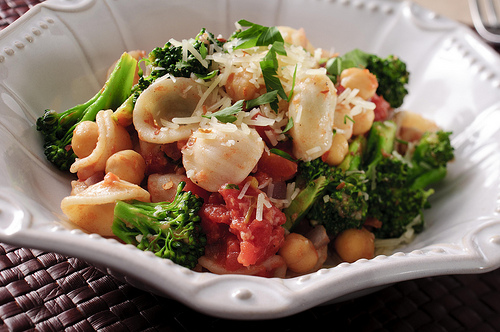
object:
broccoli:
[322, 49, 411, 108]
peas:
[280, 230, 320, 272]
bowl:
[0, 1, 500, 320]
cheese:
[255, 192, 264, 224]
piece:
[180, 123, 267, 193]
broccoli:
[110, 179, 207, 269]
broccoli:
[36, 52, 136, 175]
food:
[60, 172, 155, 237]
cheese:
[306, 147, 324, 156]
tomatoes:
[202, 183, 289, 272]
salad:
[36, 17, 455, 279]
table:
[0, 0, 500, 331]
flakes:
[348, 104, 365, 118]